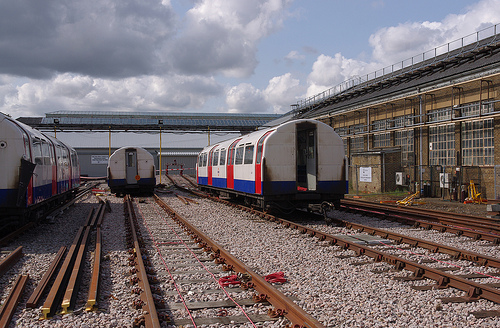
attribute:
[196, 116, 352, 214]
train car — blue, wide, long, red, bright, white , large, sitting, big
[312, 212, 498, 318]
railroad tracks — dark, brown, rusty, long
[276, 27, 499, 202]
building — large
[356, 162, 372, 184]
sign — white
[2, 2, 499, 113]
sky — blue, cloudy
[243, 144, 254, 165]
window — tinted